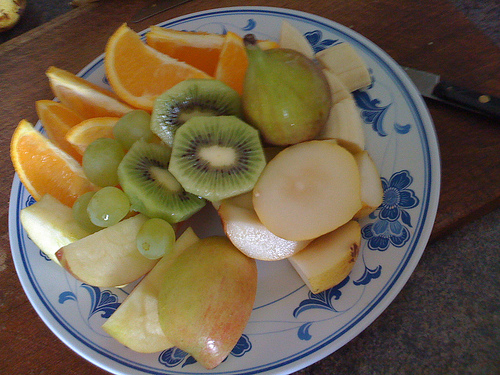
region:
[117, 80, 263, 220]
three slices of kiwi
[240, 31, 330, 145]
a large persimmon on a plate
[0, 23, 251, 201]
several orange slice sections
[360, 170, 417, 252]
blue flower design on a plate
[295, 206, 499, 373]
a marble gray counter top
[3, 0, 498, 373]
a wooden cutting board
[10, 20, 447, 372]
Fruit on b;lue and white palte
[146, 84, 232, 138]
slice of Fruit on a plate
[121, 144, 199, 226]
slice of Fruit on a plate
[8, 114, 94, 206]
slice of Fruit on a plate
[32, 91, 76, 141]
slice of Fruit on a plate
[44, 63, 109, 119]
slice of Fruit on a plate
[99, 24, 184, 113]
slice of Fruit on a plate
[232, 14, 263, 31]
Blue design on white plate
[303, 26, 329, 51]
Blue design on white plate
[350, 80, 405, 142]
Blue design on white plate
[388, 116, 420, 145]
Blue design on white plate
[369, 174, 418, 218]
Blue design on white plate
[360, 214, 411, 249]
Blue design on white plate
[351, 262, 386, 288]
Blue design on white plate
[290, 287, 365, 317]
Blue design on white plate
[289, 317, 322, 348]
Blue design on white plate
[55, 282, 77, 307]
Blue design on white plate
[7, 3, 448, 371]
a plate full of fruit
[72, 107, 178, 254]
green grapes on a plate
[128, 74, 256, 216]
three slices of kiwi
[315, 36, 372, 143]
three pieces of banana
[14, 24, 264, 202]
orange wedges beside grapes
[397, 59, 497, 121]
a black handled knife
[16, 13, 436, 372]
a white plate with a blue floral design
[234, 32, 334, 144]
a whole piece of fruit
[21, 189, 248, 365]
an apple cut into wedges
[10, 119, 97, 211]
orange slice next to grape on plate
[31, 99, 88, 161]
orange slice next to grape on plate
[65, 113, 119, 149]
orange slice next to grape on plate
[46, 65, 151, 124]
orange slice next to grape on plate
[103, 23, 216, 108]
orange slice next to grape on plate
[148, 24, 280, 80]
orange slice next to grape on plate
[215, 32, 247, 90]
orange slice next to grape on plate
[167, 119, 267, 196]
kiwi slice on top of kiwi slice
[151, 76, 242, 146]
kiwi slice below kiwi slice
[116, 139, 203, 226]
kiwi slice below kiwi slice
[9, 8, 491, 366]
a blue and white plate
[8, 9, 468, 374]
a blue and white plate on a table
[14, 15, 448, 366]
a lot of fruit on a blue and white plate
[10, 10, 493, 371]
a knife next to a blue and white plate